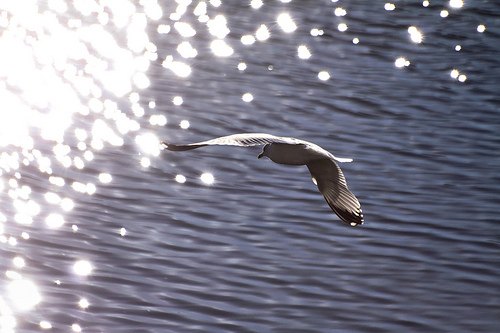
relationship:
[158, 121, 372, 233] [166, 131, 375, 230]
bird has wings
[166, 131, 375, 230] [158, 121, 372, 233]
wings on bird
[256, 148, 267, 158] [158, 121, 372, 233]
beak on bird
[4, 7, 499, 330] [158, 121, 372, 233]
water underneath bird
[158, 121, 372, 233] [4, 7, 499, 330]
bird over water